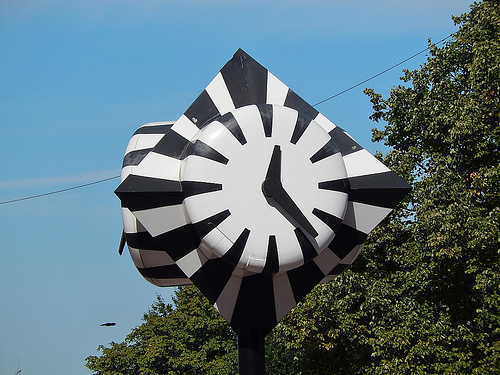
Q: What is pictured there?
A: Clock.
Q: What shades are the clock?
A: Black and white.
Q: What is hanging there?
A: Wires.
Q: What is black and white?
A: The clock.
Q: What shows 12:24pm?
A: The clock.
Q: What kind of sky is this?
A: No clouds clear sky.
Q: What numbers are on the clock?
A: There is no numbers.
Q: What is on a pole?
A: Clock face.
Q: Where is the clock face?
A: On the pole.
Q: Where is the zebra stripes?
A: On the clock.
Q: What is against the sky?
A: Telephone line.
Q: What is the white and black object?
A: Clock.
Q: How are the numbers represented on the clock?
A: Black lines.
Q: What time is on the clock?
A: 12:24.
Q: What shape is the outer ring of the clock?
A: Square.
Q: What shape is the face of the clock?
A: Round circular.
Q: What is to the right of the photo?
A: Trees.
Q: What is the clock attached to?
A: Black pole.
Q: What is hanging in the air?
A: Black power line.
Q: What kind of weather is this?
A: Sunny with no clouds.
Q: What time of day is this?
A: Daylight hours.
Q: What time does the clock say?
A: 1:25.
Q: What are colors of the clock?
A: Black and white.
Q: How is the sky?
A: Clear.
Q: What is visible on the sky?
A: A power line.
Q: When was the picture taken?
A: During the daytime.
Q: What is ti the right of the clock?
A: A tree or bush.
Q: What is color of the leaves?
A: Green.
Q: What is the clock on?
A: A pole.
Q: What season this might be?
A: Summer.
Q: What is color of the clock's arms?
A: Black.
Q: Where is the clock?
A: On a sign post.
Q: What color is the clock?
A: Black and white.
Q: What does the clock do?
A: Tell time.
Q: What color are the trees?
A: Green.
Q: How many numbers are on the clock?
A: None.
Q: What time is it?
A: 12:23.